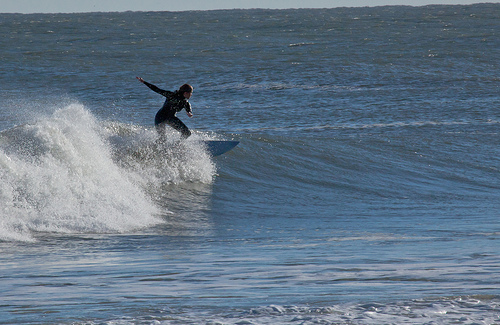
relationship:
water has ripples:
[22, 20, 439, 323] [60, 255, 148, 290]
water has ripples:
[22, 20, 439, 323] [172, 250, 452, 290]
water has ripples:
[0, 2, 499, 325] [33, 111, 283, 273]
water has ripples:
[0, 2, 499, 325] [49, 257, 466, 293]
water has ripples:
[0, 2, 499, 325] [308, 219, 483, 289]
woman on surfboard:
[131, 76, 229, 170] [154, 119, 262, 174]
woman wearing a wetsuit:
[133, 76, 192, 147] [143, 77, 190, 140]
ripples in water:
[248, 188, 418, 262] [0, 2, 499, 325]